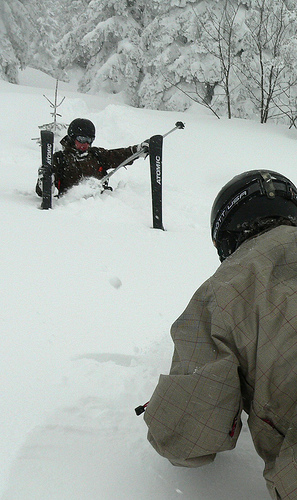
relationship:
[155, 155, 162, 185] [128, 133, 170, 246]
logo on ski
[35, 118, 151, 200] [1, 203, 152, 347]
man in snow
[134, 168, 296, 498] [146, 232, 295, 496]
person in coat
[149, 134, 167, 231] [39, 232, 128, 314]
black skis in snow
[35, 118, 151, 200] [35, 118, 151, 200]
man on man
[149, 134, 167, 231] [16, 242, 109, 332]
black skis in snow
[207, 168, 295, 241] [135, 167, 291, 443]
helmet on person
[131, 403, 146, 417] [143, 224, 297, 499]
tag on coat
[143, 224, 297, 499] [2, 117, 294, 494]
coat in snow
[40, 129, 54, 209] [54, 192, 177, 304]
ski in snow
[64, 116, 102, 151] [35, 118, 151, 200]
helmet on man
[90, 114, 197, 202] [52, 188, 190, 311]
pole in snow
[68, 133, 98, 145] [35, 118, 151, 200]
snow goggles on man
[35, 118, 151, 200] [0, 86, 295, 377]
man in snow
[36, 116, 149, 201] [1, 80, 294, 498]
man in snow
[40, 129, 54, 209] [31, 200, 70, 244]
ski buried in cnow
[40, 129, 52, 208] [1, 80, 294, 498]
ski in snow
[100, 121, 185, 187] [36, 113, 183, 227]
pole held by skier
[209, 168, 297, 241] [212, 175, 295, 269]
helmet on head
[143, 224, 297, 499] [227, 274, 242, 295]
coat has line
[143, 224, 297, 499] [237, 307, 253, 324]
coat has line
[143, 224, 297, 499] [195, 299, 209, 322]
coat has line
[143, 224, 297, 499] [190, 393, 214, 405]
coat has line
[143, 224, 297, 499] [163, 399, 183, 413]
coat has line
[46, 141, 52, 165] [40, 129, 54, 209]
writing on ski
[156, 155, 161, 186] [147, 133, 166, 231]
logo on ski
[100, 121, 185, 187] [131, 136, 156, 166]
pole in hand